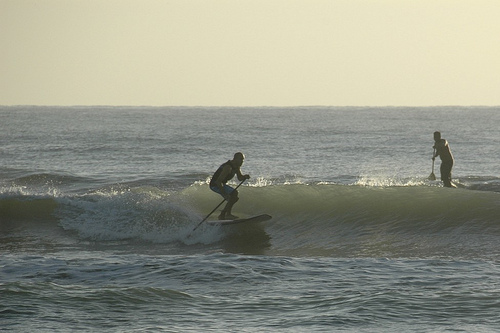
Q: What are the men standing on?
A: Surfboards.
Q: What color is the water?
A: Blue.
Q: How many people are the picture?
A: Two.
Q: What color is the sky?
A: White.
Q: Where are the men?
A: In the ocean.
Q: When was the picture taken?
A: During the day.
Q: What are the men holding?
A: Paddles.